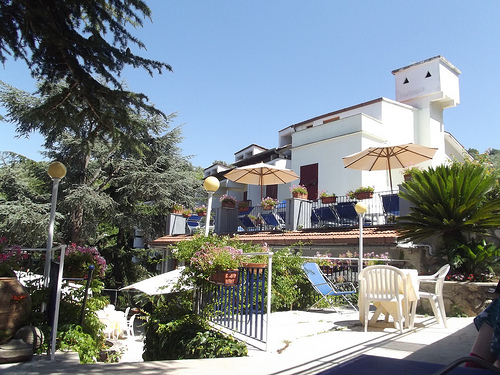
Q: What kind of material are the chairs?
A: Plastic.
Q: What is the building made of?
A: Stone.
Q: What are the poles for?
A: Lights.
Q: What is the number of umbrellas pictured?
A: 2.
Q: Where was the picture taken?
A: Outside of a house.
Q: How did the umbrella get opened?
A: A person.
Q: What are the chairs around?
A: Tables.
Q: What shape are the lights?
A: Circular.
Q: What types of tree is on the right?
A: Palm tree.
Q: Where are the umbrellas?
A: In the table.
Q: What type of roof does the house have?
A: Flat.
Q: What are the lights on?
A: Poles.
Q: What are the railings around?
A: Patios.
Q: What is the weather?
A: Sunny and warm.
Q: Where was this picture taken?
A: A private residence.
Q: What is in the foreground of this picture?
A: Lawn furniture on a patio.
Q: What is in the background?
A: A white house.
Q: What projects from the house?
A: A patio lined with umbrellas and blue chairs.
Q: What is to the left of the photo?
A: Trees and flowers.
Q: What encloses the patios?
A: Iron fencing.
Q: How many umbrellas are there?
A: Two.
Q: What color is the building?
A: White.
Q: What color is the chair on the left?
A: Blue.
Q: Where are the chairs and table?
A: Patio.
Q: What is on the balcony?
A: Plants.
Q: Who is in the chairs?
A: No one.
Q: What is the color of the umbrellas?
A: White.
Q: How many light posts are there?
A: Three.